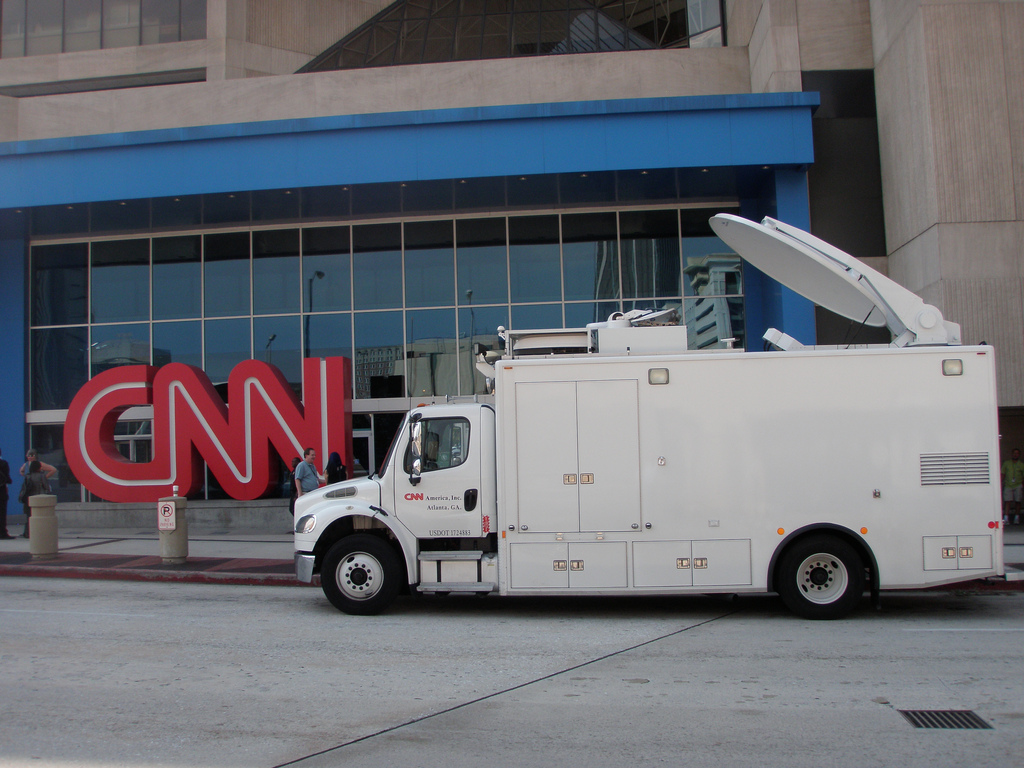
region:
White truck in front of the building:
[279, 205, 1010, 629]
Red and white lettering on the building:
[62, 344, 356, 518]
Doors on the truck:
[498, 372, 654, 544]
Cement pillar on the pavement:
[20, 486, 66, 560]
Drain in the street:
[895, 698, 995, 738]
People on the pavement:
[2, 439, 61, 545]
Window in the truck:
[400, 414, 477, 479]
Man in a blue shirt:
[277, 445, 323, 499]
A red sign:
[58, 345, 365, 516]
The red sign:
[64, 351, 349, 513]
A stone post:
[15, 485, 66, 550]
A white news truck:
[290, 197, 1000, 628]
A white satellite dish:
[691, 180, 917, 323]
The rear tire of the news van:
[791, 542, 865, 620]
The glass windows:
[20, 194, 767, 495]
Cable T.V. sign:
[61, 352, 360, 505]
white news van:
[285, 208, 1007, 626]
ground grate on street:
[898, 704, 996, 737]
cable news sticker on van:
[400, 489, 474, 515]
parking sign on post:
[155, 498, 178, 531]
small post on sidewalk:
[27, 491, 59, 561]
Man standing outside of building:
[291, 445, 318, 500]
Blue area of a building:
[0, 84, 819, 585]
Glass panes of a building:
[20, 203, 760, 501]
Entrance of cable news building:
[5, 93, 819, 543]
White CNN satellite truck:
[288, 209, 1004, 622]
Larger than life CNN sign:
[57, 351, 359, 506]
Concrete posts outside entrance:
[21, 490, 193, 570]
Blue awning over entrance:
[7, 82, 846, 232]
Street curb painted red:
[1, 545, 331, 597]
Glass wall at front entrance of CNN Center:
[23, 193, 754, 507]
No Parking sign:
[149, 497, 185, 533]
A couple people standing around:
[288, 440, 350, 508]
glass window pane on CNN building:
[23, 235, 91, 327]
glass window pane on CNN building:
[87, 236, 155, 323]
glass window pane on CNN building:
[150, 232, 206, 323]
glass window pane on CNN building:
[199, 227, 252, 318]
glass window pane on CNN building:
[248, 227, 306, 314]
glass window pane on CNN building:
[300, 223, 355, 317]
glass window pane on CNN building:
[348, 219, 406, 311]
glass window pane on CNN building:
[402, 216, 455, 305]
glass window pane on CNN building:
[28, 323, 91, 410]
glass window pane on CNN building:
[88, 320, 151, 376]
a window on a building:
[23, 244, 85, 324]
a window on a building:
[90, 238, 142, 318]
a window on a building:
[155, 234, 195, 311]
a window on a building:
[204, 225, 240, 309]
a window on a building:
[247, 229, 305, 324]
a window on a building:
[299, 223, 351, 312]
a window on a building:
[394, 212, 455, 318]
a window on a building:
[454, 216, 502, 303]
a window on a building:
[561, 209, 619, 308]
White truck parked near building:
[283, 206, 1014, 644]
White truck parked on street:
[255, 313, 1015, 627]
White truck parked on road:
[237, 278, 1013, 623]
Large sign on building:
[57, 342, 364, 494]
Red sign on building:
[40, 337, 377, 499]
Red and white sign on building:
[47, 351, 373, 498]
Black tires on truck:
[305, 527, 900, 610]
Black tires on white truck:
[309, 521, 882, 620]